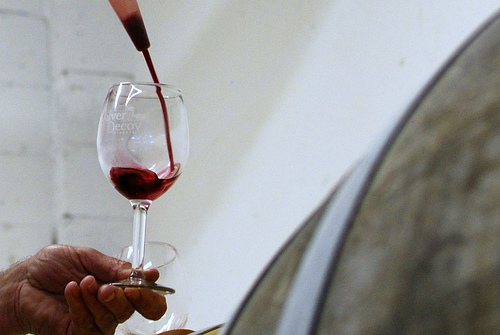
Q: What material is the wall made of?
A: Cement bricks.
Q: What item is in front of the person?
A: Wine barrel.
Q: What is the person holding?
A: A wine glass.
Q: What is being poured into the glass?
A: Wine.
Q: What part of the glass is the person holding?
A: The base.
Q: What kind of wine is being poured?
A: Red.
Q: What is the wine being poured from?
A: A bottle.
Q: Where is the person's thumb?
A: On the stem.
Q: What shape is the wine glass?
A: Oval.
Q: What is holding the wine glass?
A: A hand.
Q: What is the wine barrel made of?
A: Wood.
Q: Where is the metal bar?
A: On the wine barrel.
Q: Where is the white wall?
A: Behind the wine barrel.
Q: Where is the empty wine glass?
A: Behind the hand.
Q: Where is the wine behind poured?
A: Into the glass.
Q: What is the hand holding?
A: A wine glass.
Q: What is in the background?
A: A white wall.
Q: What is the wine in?
A: A glass.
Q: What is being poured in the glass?
A: Wine.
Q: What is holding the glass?
A: A hand.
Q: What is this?
A: Wine.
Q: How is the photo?
A: Clear.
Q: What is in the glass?
A: Drink.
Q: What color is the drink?
A: Red.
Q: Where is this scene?
A: Inside a room.